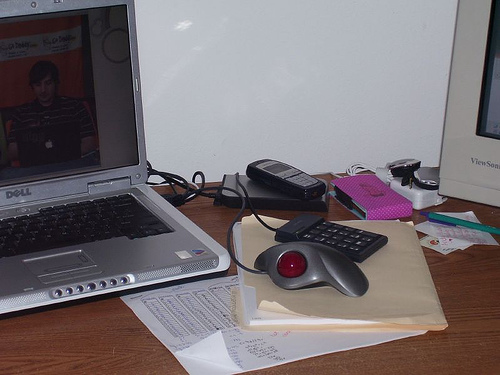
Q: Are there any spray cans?
A: No, there are no spray cans.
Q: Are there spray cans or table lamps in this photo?
A: No, there are no spray cans or table lamps.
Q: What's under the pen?
A: The papers are under the pen.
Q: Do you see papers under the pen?
A: Yes, there are papers under the pen.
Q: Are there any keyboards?
A: Yes, there is a keyboard.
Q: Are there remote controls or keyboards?
A: Yes, there is a keyboard.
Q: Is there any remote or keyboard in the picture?
A: Yes, there is a keyboard.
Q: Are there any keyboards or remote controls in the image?
A: Yes, there is a keyboard.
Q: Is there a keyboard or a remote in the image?
A: Yes, there is a keyboard.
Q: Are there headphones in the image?
A: No, there are no headphones.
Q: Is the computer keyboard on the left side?
A: Yes, the keyboard is on the left of the image.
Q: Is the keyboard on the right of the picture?
A: No, the keyboard is on the left of the image.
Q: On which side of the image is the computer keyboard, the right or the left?
A: The keyboard is on the left of the image.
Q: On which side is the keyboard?
A: The keyboard is on the left of the image.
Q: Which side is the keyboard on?
A: The keyboard is on the left of the image.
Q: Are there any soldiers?
A: No, there are no soldiers.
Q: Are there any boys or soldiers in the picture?
A: No, there are no soldiers or boys.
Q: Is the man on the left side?
A: Yes, the man is on the left of the image.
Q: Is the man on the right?
A: No, the man is on the left of the image.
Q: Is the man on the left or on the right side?
A: The man is on the left of the image.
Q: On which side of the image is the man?
A: The man is on the left of the image.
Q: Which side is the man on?
A: The man is on the left of the image.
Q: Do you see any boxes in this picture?
A: No, there are no boxes.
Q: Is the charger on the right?
A: Yes, the charger is on the right of the image.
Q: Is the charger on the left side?
A: No, the charger is on the right of the image.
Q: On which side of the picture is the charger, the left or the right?
A: The charger is on the right of the image.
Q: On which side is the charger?
A: The charger is on the right of the image.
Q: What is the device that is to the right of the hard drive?
A: The device is a charger.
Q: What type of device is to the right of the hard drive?
A: The device is a charger.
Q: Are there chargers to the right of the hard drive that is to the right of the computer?
A: Yes, there is a charger to the right of the hard drive.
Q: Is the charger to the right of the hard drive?
A: Yes, the charger is to the right of the hard drive.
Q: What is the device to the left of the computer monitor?
A: The device is a charger.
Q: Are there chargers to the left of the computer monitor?
A: Yes, there is a charger to the left of the computer monitor.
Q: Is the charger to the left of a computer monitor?
A: Yes, the charger is to the left of a computer monitor.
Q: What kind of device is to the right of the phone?
A: The device is a charger.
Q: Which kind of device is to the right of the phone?
A: The device is a charger.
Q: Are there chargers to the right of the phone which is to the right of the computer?
A: Yes, there is a charger to the right of the phone.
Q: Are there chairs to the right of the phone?
A: No, there is a charger to the right of the phone.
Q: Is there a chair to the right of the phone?
A: No, there is a charger to the right of the phone.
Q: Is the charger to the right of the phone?
A: Yes, the charger is to the right of the phone.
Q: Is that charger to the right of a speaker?
A: No, the charger is to the right of the phone.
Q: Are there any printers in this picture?
A: No, there are no printers.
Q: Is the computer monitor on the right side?
A: Yes, the computer monitor is on the right of the image.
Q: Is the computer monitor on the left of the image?
A: No, the computer monitor is on the right of the image.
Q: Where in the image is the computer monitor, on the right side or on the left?
A: The computer monitor is on the right of the image.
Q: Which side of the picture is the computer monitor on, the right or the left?
A: The computer monitor is on the right of the image.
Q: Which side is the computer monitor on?
A: The computer monitor is on the right of the image.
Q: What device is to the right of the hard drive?
A: The device is a computer monitor.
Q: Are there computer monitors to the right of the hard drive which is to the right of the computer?
A: Yes, there is a computer monitor to the right of the hard drive.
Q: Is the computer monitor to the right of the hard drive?
A: Yes, the computer monitor is to the right of the hard drive.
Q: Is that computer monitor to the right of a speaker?
A: No, the computer monitor is to the right of the hard drive.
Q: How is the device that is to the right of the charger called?
A: The device is a computer monitor.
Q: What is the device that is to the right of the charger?
A: The device is a computer monitor.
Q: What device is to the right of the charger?
A: The device is a computer monitor.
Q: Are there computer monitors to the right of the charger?
A: Yes, there is a computer monitor to the right of the charger.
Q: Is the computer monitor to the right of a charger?
A: Yes, the computer monitor is to the right of a charger.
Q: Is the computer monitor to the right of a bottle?
A: No, the computer monitor is to the right of a charger.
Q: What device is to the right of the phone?
A: The device is a computer monitor.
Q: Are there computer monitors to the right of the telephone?
A: Yes, there is a computer monitor to the right of the telephone.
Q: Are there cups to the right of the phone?
A: No, there is a computer monitor to the right of the phone.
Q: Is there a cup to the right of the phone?
A: No, there is a computer monitor to the right of the phone.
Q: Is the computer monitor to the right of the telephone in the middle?
A: Yes, the computer monitor is to the right of the telephone.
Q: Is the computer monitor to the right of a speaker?
A: No, the computer monitor is to the right of the telephone.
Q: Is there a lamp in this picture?
A: No, there are no lamps.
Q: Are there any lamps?
A: No, there are no lamps.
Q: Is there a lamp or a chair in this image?
A: No, there are no lamps or chairs.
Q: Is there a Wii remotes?
A: No, there are no Wii controllers.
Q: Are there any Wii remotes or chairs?
A: No, there are no Wii remotes or chairs.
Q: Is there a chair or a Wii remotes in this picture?
A: No, there are no Wii controllers or chairs.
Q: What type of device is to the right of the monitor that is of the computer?
A: The device is a hard drive.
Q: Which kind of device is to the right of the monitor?
A: The device is a hard drive.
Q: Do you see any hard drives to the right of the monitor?
A: Yes, there is a hard drive to the right of the monitor.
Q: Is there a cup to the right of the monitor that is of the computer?
A: No, there is a hard drive to the right of the monitor.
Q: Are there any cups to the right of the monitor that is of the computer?
A: No, there is a hard drive to the right of the monitor.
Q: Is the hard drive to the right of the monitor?
A: Yes, the hard drive is to the right of the monitor.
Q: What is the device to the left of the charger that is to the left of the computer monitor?
A: The device is a hard drive.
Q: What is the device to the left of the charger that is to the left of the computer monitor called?
A: The device is a hard drive.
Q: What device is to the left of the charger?
A: The device is a hard drive.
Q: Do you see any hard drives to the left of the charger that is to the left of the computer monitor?
A: Yes, there is a hard drive to the left of the charger.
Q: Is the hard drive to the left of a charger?
A: Yes, the hard drive is to the left of a charger.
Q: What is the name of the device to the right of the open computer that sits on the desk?
A: The device is a hard drive.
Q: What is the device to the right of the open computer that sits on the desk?
A: The device is a hard drive.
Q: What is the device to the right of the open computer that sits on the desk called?
A: The device is a hard drive.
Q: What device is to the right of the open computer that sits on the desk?
A: The device is a hard drive.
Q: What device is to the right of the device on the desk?
A: The device is a hard drive.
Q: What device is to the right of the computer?
A: The device is a hard drive.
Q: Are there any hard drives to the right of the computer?
A: Yes, there is a hard drive to the right of the computer.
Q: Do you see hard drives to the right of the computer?
A: Yes, there is a hard drive to the right of the computer.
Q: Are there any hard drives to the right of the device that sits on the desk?
A: Yes, there is a hard drive to the right of the computer.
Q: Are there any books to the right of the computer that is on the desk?
A: No, there is a hard drive to the right of the computer.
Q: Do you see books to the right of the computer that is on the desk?
A: No, there is a hard drive to the right of the computer.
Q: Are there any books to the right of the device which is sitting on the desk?
A: No, there is a hard drive to the right of the computer.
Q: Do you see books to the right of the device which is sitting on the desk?
A: No, there is a hard drive to the right of the computer.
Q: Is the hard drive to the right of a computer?
A: Yes, the hard drive is to the right of a computer.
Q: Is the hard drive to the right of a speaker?
A: No, the hard drive is to the right of a computer.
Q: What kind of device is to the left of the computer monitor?
A: The device is a hard drive.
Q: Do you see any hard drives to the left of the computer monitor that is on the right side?
A: Yes, there is a hard drive to the left of the computer monitor.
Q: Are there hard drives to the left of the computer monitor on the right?
A: Yes, there is a hard drive to the left of the computer monitor.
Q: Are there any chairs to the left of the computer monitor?
A: No, there is a hard drive to the left of the computer monitor.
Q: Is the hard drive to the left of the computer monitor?
A: Yes, the hard drive is to the left of the computer monitor.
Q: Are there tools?
A: No, there are no tools.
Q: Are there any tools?
A: No, there are no tools.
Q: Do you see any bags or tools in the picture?
A: No, there are no tools or bags.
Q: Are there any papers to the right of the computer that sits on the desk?
A: Yes, there are papers to the right of the computer.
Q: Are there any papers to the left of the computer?
A: No, the papers are to the right of the computer.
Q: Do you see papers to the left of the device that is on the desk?
A: No, the papers are to the right of the computer.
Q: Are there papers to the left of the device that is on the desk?
A: No, the papers are to the right of the computer.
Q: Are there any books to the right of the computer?
A: No, there are papers to the right of the computer.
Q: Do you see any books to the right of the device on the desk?
A: No, there are papers to the right of the computer.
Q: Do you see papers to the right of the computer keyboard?
A: Yes, there are papers to the right of the keyboard.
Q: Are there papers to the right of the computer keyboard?
A: Yes, there are papers to the right of the keyboard.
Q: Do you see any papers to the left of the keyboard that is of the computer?
A: No, the papers are to the right of the keyboard.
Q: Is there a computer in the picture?
A: Yes, there is a computer.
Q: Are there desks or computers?
A: Yes, there is a computer.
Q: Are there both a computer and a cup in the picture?
A: No, there is a computer but no cups.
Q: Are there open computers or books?
A: Yes, there is an open computer.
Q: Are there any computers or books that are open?
A: Yes, the computer is open.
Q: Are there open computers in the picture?
A: Yes, there is an open computer.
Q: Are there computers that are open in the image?
A: Yes, there is an open computer.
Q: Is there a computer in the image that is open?
A: Yes, there is an open computer.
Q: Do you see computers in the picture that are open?
A: Yes, there is a computer that is open.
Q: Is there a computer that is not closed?
A: Yes, there is a open computer.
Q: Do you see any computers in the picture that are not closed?
A: Yes, there is a open computer.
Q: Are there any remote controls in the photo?
A: No, there are no remote controls.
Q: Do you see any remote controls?
A: No, there are no remote controls.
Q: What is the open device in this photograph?
A: The device is a computer.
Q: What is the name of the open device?
A: The device is a computer.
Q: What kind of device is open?
A: The device is a computer.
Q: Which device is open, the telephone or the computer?
A: The computer is open.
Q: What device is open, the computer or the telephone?
A: The computer is open.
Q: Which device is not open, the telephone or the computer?
A: The telephone is not open.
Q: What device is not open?
A: The device is a phone.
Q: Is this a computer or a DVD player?
A: This is a computer.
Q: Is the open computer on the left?
A: Yes, the computer is on the left of the image.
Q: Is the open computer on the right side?
A: No, the computer is on the left of the image.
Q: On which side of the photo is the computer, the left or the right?
A: The computer is on the left of the image.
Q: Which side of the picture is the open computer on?
A: The computer is on the left of the image.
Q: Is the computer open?
A: Yes, the computer is open.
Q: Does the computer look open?
A: Yes, the computer is open.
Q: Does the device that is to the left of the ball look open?
A: Yes, the computer is open.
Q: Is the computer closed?
A: No, the computer is open.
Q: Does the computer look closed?
A: No, the computer is open.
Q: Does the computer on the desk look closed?
A: No, the computer is open.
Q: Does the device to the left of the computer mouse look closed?
A: No, the computer is open.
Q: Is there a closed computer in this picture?
A: No, there is a computer but it is open.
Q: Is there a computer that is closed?
A: No, there is a computer but it is open.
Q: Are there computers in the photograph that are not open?
A: No, there is a computer but it is open.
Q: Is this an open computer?
A: Yes, this is an open computer.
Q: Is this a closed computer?
A: No, this is an open computer.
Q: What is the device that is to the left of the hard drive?
A: The device is a computer.